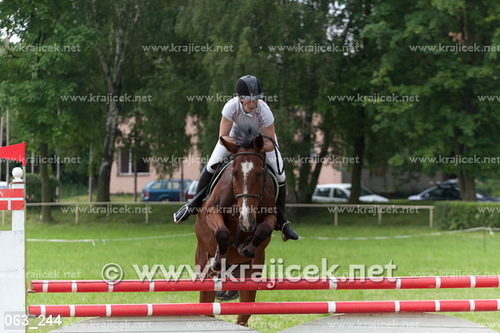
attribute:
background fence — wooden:
[30, 199, 440, 234]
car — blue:
[141, 174, 195, 205]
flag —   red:
[2, 140, 29, 165]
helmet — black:
[230, 73, 261, 99]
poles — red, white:
[142, 276, 300, 317]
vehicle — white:
[312, 182, 387, 204]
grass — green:
[97, 242, 136, 252]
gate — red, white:
[32, 267, 497, 321]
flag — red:
[0, 132, 35, 218]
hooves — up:
[207, 239, 259, 279]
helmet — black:
[232, 68, 265, 100]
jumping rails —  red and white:
[28, 275, 499, 320]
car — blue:
[144, 173, 192, 210]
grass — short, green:
[318, 219, 481, 262]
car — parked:
[407, 178, 499, 200]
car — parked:
[315, 181, 388, 206]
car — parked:
[139, 176, 191, 200]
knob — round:
[11, 166, 23, 181]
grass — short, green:
[376, 233, 469, 280]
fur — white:
[235, 155, 255, 227]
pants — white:
[209, 142, 287, 208]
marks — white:
[40, 271, 483, 329]